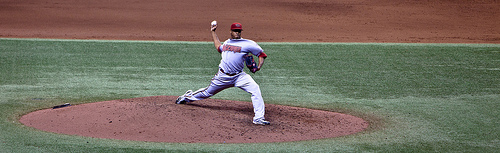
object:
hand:
[209, 24, 219, 31]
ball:
[211, 20, 217, 25]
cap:
[228, 22, 245, 31]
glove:
[245, 56, 257, 71]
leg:
[175, 73, 221, 104]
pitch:
[4, 38, 96, 59]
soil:
[39, 106, 184, 130]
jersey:
[218, 36, 248, 76]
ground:
[27, 92, 353, 152]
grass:
[429, 69, 498, 90]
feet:
[239, 118, 281, 127]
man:
[197, 22, 265, 125]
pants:
[191, 71, 268, 121]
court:
[6, 2, 489, 57]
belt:
[217, 74, 243, 80]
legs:
[239, 77, 272, 125]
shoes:
[248, 118, 270, 124]